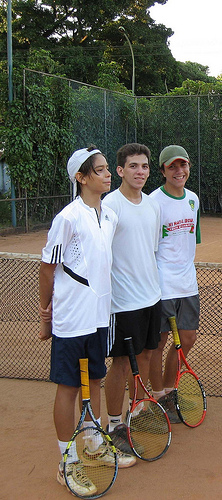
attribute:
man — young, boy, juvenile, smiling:
[149, 144, 202, 425]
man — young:
[106, 140, 168, 449]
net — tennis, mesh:
[2, 250, 221, 397]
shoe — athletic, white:
[56, 460, 96, 496]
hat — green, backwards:
[159, 142, 190, 166]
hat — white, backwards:
[67, 144, 103, 200]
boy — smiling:
[40, 144, 137, 494]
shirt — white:
[40, 194, 120, 339]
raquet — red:
[167, 314, 206, 427]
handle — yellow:
[166, 314, 181, 348]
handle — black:
[123, 336, 137, 376]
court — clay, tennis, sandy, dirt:
[2, 214, 217, 498]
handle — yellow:
[79, 358, 92, 402]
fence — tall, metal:
[3, 63, 221, 215]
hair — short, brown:
[116, 143, 150, 168]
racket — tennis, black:
[121, 334, 174, 462]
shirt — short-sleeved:
[150, 185, 201, 297]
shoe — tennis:
[81, 441, 139, 468]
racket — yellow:
[62, 355, 122, 497]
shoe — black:
[105, 424, 144, 456]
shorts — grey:
[162, 299, 200, 332]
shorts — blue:
[51, 328, 106, 384]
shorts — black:
[111, 299, 161, 354]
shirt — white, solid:
[103, 188, 163, 313]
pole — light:
[5, 2, 17, 228]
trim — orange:
[162, 158, 189, 166]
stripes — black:
[49, 243, 62, 263]